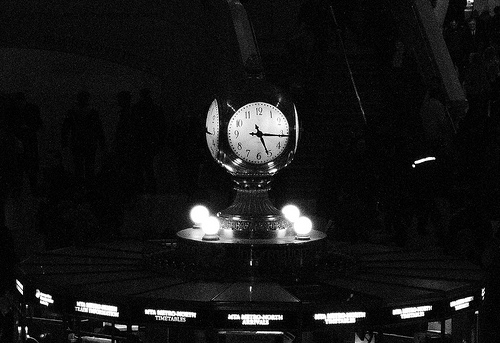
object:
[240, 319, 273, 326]
words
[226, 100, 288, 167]
clock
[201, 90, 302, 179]
4 sides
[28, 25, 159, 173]
dark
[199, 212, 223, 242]
lights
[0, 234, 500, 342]
black table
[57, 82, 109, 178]
people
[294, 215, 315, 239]
bulbs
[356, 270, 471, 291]
stairs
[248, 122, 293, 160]
5:16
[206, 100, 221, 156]
clock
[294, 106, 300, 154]
clock